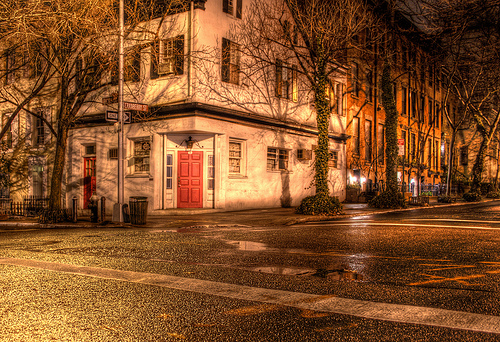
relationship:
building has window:
[63, 0, 348, 214] [273, 56, 298, 101]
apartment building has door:
[5, 6, 492, 211] [170, 146, 208, 208]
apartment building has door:
[5, 6, 492, 211] [80, 154, 99, 212]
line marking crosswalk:
[0, 255, 500, 336] [87, 231, 362, 327]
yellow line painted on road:
[306, 218, 499, 228] [1, 197, 499, 340]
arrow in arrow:
[107, 112, 129, 121] [105, 109, 120, 121]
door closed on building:
[177, 150, 204, 207] [3, 5, 485, 223]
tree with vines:
[226, 0, 383, 217] [296, 79, 344, 214]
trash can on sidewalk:
[125, 192, 155, 244] [0, 206, 166, 233]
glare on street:
[342, 205, 377, 275] [288, 220, 484, 317]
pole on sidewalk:
[76, 17, 157, 253] [118, 178, 289, 240]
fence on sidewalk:
[0, 194, 49, 218] [3, 210, 112, 240]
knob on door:
[171, 171, 191, 189] [174, 150, 204, 210]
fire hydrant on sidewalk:
[86, 193, 99, 221] [2, 187, 498, 226]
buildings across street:
[0, 0, 498, 219] [2, 200, 351, 239]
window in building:
[256, 134, 296, 184] [90, 21, 334, 200]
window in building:
[216, 29, 253, 86] [75, 13, 338, 204]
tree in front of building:
[226, 1, 395, 193] [0, 0, 348, 214]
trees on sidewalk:
[11, 0, 193, 168] [8, 217, 122, 227]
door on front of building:
[177, 150, 204, 207] [0, 0, 348, 214]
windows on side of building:
[66, 35, 246, 87] [0, 0, 348, 214]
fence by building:
[0, 194, 49, 218] [78, 9, 328, 196]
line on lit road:
[11, 247, 498, 338] [0, 198, 500, 341]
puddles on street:
[36, 232, 116, 254] [234, 198, 461, 312]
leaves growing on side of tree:
[314, 149, 326, 176] [230, 0, 395, 231]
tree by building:
[226, 0, 383, 217] [3, 5, 485, 223]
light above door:
[175, 137, 207, 154] [177, 150, 202, 207]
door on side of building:
[83, 152, 95, 209] [63, 0, 348, 214]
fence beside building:
[3, 192, 54, 220] [3, 5, 485, 223]